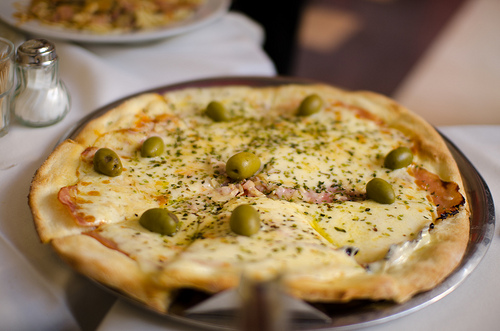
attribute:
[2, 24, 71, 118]
salt shaker — glass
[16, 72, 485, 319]
pizza pan — metal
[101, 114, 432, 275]
pizza — small, sliced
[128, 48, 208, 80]
tablecloth — white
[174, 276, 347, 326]
spatula — metal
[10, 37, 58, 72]
top — metal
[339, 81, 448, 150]
pizza crust — brown